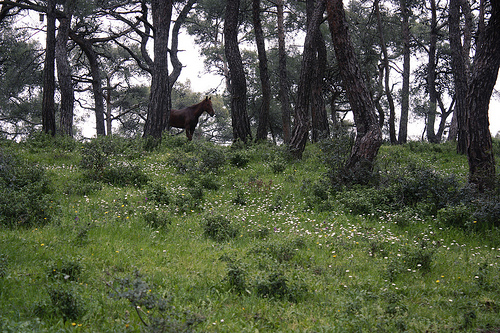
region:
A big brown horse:
[140, 98, 220, 145]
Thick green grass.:
[58, 225, 211, 278]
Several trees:
[245, 35, 495, 125]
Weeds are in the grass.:
[255, 205, 455, 272]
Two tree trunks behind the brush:
[30, 116, 86, 144]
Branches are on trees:
[7, 30, 38, 115]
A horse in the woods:
[147, 95, 263, 167]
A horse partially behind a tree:
[142, 91, 228, 146]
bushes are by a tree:
[386, 161, 497, 241]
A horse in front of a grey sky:
[183, 50, 264, 160]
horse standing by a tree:
[145, 69, 215, 143]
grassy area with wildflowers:
[53, 154, 360, 314]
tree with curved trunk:
[308, 16, 397, 185]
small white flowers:
[253, 207, 385, 247]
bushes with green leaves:
[392, 158, 493, 230]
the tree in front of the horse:
[140, 17, 170, 158]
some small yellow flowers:
[82, 200, 135, 226]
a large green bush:
[0, 135, 65, 230]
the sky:
[182, 53, 197, 83]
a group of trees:
[223, 24, 392, 179]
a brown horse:
[169, 95, 216, 147]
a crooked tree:
[325, 0, 383, 185]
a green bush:
[0, 150, 58, 229]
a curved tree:
[466, 1, 499, 192]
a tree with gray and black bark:
[150, 0, 172, 150]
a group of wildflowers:
[206, 190, 457, 252]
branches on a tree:
[87, 32, 154, 77]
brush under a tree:
[321, 135, 498, 223]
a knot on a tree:
[354, 118, 385, 167]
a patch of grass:
[2, 227, 93, 332]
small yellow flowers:
[68, 318, 87, 330]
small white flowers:
[229, 195, 369, 240]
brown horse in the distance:
[163, 90, 220, 143]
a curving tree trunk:
[332, 63, 387, 191]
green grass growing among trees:
[8, 140, 487, 327]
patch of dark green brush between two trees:
[357, 145, 483, 217]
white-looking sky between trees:
[168, 8, 304, 90]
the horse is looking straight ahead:
[160, 87, 222, 117]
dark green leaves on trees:
[0, 33, 38, 88]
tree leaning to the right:
[283, 1, 328, 160]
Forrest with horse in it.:
[14, 29, 499, 226]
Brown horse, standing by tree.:
[165, 87, 218, 148]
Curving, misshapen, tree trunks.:
[331, 27, 497, 189]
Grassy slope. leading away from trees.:
[9, 129, 498, 329]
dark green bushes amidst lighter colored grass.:
[5, 146, 145, 219]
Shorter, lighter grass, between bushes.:
[57, 192, 287, 327]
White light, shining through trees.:
[80, 25, 391, 150]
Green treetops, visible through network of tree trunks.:
[7, 18, 490, 148]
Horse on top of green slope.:
[168, 77, 336, 313]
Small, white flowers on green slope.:
[231, 176, 458, 274]